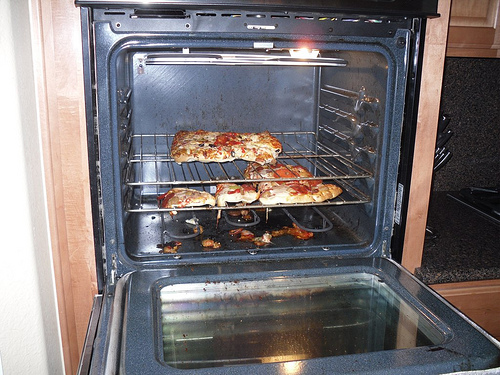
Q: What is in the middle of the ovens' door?
A: A window.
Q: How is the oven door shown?
A: Open.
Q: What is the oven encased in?
A: Wood.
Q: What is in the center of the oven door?
A: Clear window.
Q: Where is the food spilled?
A: On the oven bottom.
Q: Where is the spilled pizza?
A: In an oven.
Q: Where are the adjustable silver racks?
A: In the oven.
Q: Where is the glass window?
A: In the oven door.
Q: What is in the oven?
A: Pizza.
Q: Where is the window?
A: On the gray open oven door.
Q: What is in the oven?
A: Pizza.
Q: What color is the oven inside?
A: Gray.